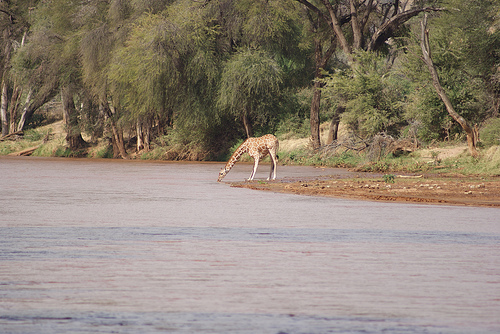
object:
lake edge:
[1, 142, 498, 204]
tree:
[134, 101, 143, 152]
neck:
[223, 145, 248, 173]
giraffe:
[217, 133, 280, 183]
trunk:
[111, 121, 127, 157]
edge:
[0, 145, 500, 176]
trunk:
[111, 131, 120, 158]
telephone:
[212, 126, 283, 186]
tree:
[71, 0, 119, 145]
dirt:
[222, 170, 500, 208]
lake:
[0, 154, 498, 334]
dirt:
[0, 154, 274, 167]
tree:
[317, 50, 391, 141]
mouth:
[217, 179, 222, 182]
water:
[0, 154, 500, 334]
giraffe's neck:
[225, 142, 249, 173]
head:
[216, 165, 228, 183]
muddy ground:
[232, 175, 500, 206]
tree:
[251, 5, 338, 155]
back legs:
[267, 146, 279, 179]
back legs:
[268, 153, 275, 179]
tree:
[419, 11, 479, 155]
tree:
[216, 44, 280, 139]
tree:
[11, 0, 89, 150]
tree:
[0, 11, 36, 133]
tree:
[394, 2, 497, 141]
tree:
[227, 0, 306, 89]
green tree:
[107, 0, 215, 121]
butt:
[265, 134, 278, 149]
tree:
[320, 0, 446, 64]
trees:
[163, 0, 252, 60]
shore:
[0, 138, 500, 179]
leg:
[251, 152, 263, 178]